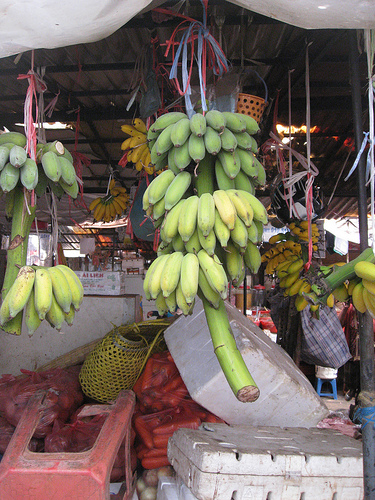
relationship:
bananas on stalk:
[5, 116, 267, 345] [191, 103, 258, 407]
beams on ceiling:
[343, 26, 375, 494] [0, 1, 366, 217]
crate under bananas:
[149, 427, 362, 499] [5, 116, 267, 345]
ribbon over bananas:
[169, 14, 224, 111] [5, 116, 267, 345]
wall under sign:
[8, 293, 141, 379] [79, 273, 132, 300]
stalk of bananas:
[191, 103, 258, 407] [5, 116, 267, 345]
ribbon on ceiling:
[169, 14, 224, 111] [0, 1, 366, 217]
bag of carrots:
[8, 367, 98, 455] [131, 347, 222, 466]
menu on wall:
[256, 219, 327, 261] [258, 97, 359, 335]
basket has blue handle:
[236, 67, 267, 122] [233, 71, 271, 98]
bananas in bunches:
[5, 116, 267, 345] [89, 185, 134, 227]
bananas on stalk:
[5, 116, 267, 345] [4, 117, 42, 335]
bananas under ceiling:
[5, 116, 267, 345] [0, 1, 366, 217]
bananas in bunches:
[0, 110, 375, 337] [89, 185, 134, 227]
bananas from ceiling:
[0, 110, 375, 337] [0, 1, 366, 217]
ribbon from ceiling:
[169, 14, 224, 111] [0, 1, 366, 217]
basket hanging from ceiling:
[236, 67, 267, 122] [0, 1, 366, 217]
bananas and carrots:
[5, 116, 267, 345] [131, 347, 222, 466]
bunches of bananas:
[89, 185, 134, 227] [0, 110, 375, 337]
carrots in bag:
[131, 347, 222, 466] [8, 367, 98, 455]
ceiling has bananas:
[0, 1, 366, 217] [263, 225, 371, 312]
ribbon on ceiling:
[284, 27, 325, 231] [0, 1, 366, 217]